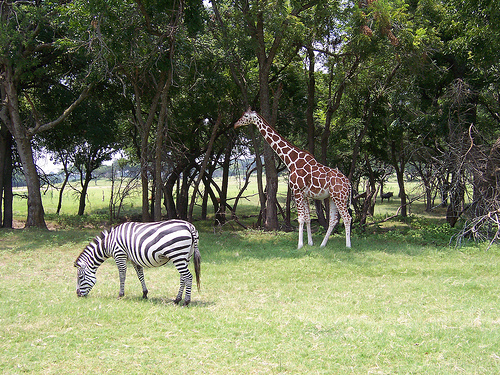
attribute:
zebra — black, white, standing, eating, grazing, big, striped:
[75, 220, 204, 307]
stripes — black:
[118, 223, 191, 266]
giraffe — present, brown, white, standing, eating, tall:
[234, 107, 358, 249]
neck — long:
[257, 120, 299, 170]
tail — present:
[191, 224, 201, 290]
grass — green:
[0, 229, 499, 374]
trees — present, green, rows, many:
[3, 2, 499, 229]